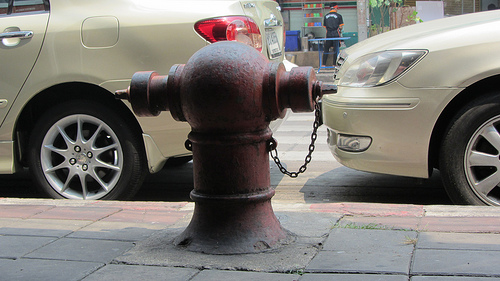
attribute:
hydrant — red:
[113, 38, 340, 259]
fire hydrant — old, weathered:
[110, 33, 340, 255]